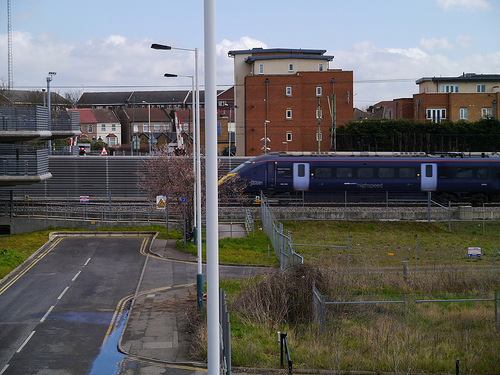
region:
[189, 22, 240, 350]
the pole is white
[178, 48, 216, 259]
the pole is white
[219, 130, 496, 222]
the train is purple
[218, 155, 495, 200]
a blue passenger train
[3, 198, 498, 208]
a set of train tracks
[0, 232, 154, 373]
a dead end road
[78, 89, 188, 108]
large building in distance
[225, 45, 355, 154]
large building in distance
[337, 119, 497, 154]
a row of tall green trees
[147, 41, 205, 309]
a tall overhead street light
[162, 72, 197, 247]
a tall overhead street light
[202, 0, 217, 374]
a tall white pole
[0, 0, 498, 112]
a cloudy blue sky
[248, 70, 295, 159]
the buiding is red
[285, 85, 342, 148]
the buiding is red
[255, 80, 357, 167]
the buiding is red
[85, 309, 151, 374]
a puddle of water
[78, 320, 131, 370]
a puddle of water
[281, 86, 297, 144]
The window frames are white.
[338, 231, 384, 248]
The grass in the background is green.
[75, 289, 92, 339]
The pavement is black.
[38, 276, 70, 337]
The pavement has white stripes.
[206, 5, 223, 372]
The light pole is tall.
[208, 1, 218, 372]
The light pole is white.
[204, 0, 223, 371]
The light pole is made from metal.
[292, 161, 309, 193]
The train door is white.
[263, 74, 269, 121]
The pole on the building is grey.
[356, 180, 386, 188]
The writing on the side of the train is yellow.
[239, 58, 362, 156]
Tall brown building with alot of windows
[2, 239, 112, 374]
White stripes in the road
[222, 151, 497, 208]
Blue and yellow train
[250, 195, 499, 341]
Silver chain link fence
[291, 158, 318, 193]
White door on train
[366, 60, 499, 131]
Brown and tan apartment buildings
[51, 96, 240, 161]
Row of buildings in the distance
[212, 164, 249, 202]
Yellow nose of train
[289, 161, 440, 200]
Two white doors on train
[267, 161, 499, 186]
Row of windows on the train